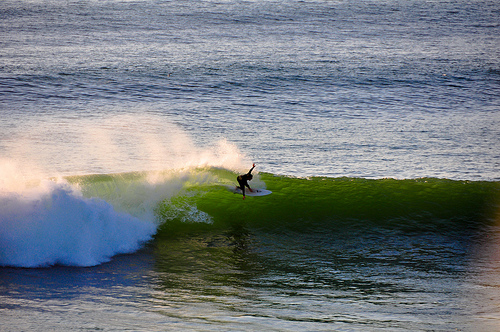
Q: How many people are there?
A: 1.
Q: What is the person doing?
A: Surfing.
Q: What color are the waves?
A: White.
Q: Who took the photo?
A: Friend.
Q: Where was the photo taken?
A: Ocean.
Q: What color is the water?
A: Blue.